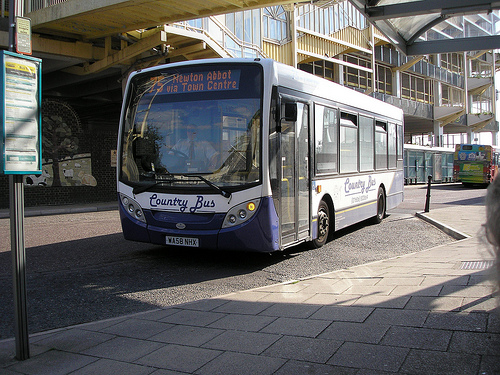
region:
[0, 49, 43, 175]
A light blue bus schedule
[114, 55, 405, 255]
A blue and white bus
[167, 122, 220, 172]
A bus driver wearing a tie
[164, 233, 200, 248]
The front license plate on the bus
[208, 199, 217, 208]
A cursive letter S on the front of the bus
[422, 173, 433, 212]
A black pole at a bus stop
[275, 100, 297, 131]
The sideview mirror on the bus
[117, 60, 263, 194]
The front windshield on the bus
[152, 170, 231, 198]
The front windshield wiper on the bus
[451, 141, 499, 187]
A blue, green and pink bus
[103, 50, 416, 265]
bus on road beside sidewalk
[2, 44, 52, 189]
sign hanging on post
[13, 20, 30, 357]
post holds a sign and a sticker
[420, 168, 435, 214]
pole on corner of sidewalk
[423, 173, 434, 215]
pole on sidewalk is black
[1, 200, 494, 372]
sidewalk is concrete brick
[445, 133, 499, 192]
colorful bus parked by building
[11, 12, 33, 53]
sticker above sign on pole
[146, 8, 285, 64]
stairs in front of building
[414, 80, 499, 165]
clear sky shining through windows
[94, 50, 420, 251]
Bus on the road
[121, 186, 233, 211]
Country Bus written on front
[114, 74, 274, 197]
One large windshield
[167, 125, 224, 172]
Bus driver sitting in the bus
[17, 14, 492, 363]
Photo taken during the day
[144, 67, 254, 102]
Bus heading to Newton Abbot via Town Centre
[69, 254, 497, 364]
Sidewalk made of concrete pavers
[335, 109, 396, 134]
Two open windows on the bus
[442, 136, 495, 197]
Colorful bus heading away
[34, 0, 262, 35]
Walkway overhead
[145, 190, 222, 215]
Country Bus written on the bus.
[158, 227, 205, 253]
The front license plate on the bus.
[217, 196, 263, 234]
Only one light is on.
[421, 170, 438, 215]
Pole on the curb.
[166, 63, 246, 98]
Destination on the bus.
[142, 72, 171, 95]
75 on the bus.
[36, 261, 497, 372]
The sidewalk is brick.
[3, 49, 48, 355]
Sign on a pole.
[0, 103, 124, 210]
The wall is brick.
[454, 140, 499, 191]
Bus in the background.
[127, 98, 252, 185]
windshield on the bus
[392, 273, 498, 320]
shadow on the ground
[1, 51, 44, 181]
a sign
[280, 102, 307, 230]
the door on the bus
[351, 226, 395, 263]
the street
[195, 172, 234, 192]
the windshield wipers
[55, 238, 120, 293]
shadow on the ground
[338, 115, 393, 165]
windows on the bus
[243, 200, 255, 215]
headlights on bus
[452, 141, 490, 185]
a bus